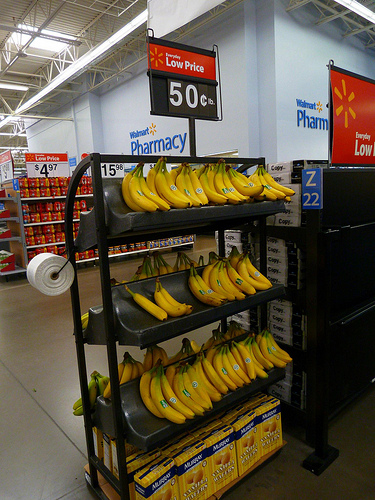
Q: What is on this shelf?
A: Bananas.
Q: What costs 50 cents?
A: Bananas.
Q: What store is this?
A: Walmart.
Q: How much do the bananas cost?
A: 50 cents.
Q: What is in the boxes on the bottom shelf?
A: Vanilla wafers.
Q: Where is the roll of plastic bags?
A: Side of the shelf.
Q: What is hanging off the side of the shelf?
A: Plastic bags.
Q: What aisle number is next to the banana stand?
A: Z 22.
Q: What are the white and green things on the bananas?
A: Stickers.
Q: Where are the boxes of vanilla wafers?
A: Bottom shelf.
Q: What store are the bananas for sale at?
A: Walmart.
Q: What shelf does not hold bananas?
A: Bottom.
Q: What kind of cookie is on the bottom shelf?
A: Wafer cookies.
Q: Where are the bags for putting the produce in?
A: On a roll, on the end of the rack with the bananas.